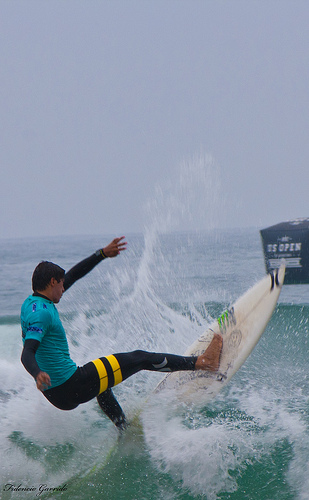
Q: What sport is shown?
A: Surfing.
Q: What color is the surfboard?
A: White.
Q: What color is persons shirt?
A: Blue.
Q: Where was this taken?
A: Beach.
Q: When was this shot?
A: Daytime.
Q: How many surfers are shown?
A: 1.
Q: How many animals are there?
A: 0.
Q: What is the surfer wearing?
A: Wetsuit.